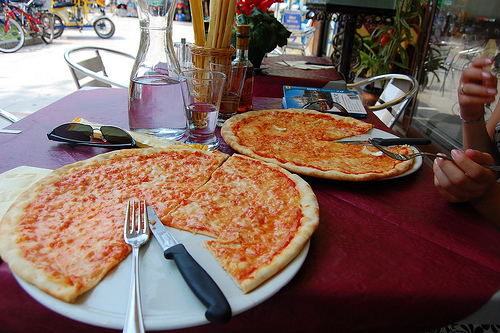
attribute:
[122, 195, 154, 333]
fork — silver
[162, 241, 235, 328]
handle — black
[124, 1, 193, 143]
vase — half filled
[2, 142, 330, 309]
pizza — cheese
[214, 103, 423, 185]
pizza — cheese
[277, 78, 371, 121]
book — tour guide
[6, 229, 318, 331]
plate — white